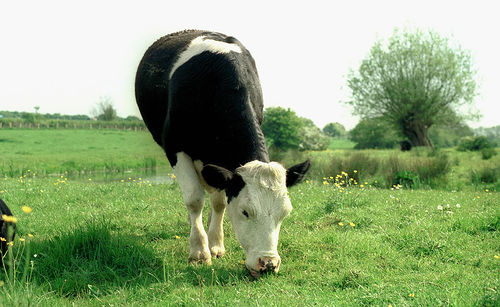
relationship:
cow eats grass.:
[132, 29, 313, 279] [133, 30, 312, 280]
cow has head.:
[132, 29, 313, 279] [195, 157, 311, 283]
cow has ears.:
[132, 29, 313, 279] [194, 158, 317, 192]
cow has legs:
[132, 29, 313, 279] [173, 160, 210, 257]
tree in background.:
[346, 29, 479, 149] [3, 3, 497, 150]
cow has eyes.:
[132, 29, 313, 279] [236, 209, 293, 221]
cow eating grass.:
[132, 29, 313, 279] [133, 30, 312, 280]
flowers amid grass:
[316, 164, 366, 194] [3, 127, 471, 305]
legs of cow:
[162, 136, 230, 270] [132, 29, 313, 279]